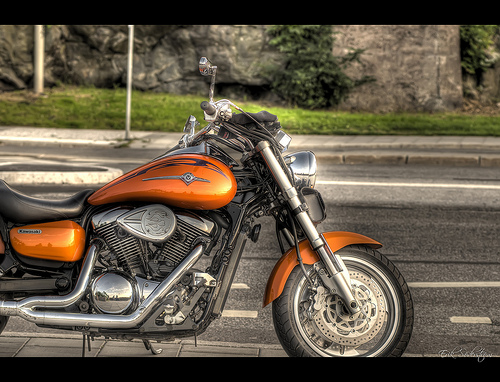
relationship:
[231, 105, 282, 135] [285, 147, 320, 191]
gloves above headlights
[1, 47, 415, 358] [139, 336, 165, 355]
motorcycle on kickstand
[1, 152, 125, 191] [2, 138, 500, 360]
island in street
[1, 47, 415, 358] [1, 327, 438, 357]
motorcycle on sidewalk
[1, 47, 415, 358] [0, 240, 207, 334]
motorcycle have pipes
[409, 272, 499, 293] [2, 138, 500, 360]
line in street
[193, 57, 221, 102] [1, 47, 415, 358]
mirror on motorcycle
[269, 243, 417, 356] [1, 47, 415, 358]
wheel on motorcycle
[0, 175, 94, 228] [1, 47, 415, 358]
seat of motorcycle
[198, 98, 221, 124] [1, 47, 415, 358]
handlebar of motorcycle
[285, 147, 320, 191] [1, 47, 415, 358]
headlights on motorcycle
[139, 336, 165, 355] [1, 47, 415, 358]
kickstand holding motorcycle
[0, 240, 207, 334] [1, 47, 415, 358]
pipes on motorcycle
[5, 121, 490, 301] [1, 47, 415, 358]
street behind motorcycle